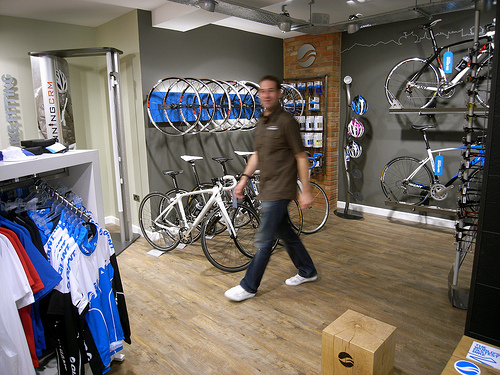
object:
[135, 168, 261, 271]
bicycle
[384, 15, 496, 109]
bicycle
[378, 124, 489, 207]
bicycle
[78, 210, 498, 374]
floor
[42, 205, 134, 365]
blue/white bikesuits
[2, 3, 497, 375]
room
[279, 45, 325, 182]
metal logo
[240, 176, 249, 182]
wrist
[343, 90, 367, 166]
toy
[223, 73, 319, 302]
man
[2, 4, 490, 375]
store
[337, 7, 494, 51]
design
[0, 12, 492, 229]
wall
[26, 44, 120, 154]
rack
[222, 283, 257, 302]
shoe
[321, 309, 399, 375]
block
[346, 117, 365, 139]
helmet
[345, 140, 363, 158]
helmet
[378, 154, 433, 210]
tire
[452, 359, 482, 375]
sticker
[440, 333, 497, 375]
box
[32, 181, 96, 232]
rack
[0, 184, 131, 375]
clothing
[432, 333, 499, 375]
package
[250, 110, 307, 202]
brown shirt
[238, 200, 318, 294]
jeans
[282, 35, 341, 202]
brick wall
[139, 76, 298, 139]
row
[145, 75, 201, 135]
tire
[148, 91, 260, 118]
rack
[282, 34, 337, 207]
corner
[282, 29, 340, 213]
wall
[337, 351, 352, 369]
logo